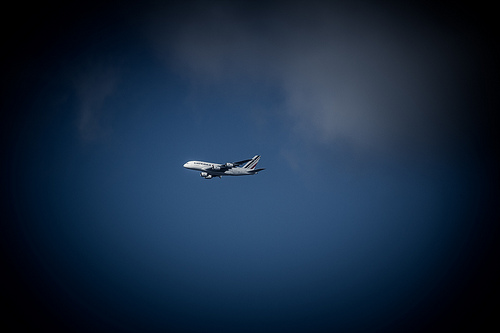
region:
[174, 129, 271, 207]
airplane flying in the sky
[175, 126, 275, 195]
airplane flying in the sky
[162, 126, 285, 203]
airplane flying in the sky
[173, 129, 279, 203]
airplane flying in the sky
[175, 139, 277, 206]
airplane flying in the sky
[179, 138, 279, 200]
airplane flying in the sky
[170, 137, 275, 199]
airplane flying in the sky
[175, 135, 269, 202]
airplane flying in the sky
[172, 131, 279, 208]
airplane flying in the sky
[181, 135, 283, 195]
airplane flying in the sky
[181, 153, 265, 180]
small white passenger plane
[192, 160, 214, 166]
line of windows on an airplane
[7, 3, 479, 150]
white clouds in the sky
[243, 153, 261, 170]
dark stripes on tail fin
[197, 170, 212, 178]
two round airplane engines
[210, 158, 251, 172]
two engines underneath a wing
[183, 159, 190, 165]
windows of the cockpit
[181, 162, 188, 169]
white rounded nose of an airplane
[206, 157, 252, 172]
dark underside of airplane wing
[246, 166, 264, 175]
small back wing section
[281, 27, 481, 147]
cloud in the sky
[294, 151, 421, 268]
clear part of the sky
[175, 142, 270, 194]
airplane in the sky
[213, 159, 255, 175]
the wing of a airplane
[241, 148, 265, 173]
the tail of an airplane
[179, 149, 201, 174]
the nose of an airplane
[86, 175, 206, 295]
a clear part of the sky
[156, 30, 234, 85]
cloud in the sky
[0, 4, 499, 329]
photo focused on airplane in the sky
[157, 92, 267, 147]
clear part of the sky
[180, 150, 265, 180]
airplane in the sky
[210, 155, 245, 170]
wing of a plane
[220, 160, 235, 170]
engine of a plane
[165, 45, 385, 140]
part of a cloudy sky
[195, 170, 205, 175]
right engine of a plane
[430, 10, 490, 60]
black area of an image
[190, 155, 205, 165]
writings on side of plane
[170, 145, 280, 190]
plane flying high.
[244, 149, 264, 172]
tale of an airplane.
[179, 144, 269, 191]
Plane in the air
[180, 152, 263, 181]
Plane is in the air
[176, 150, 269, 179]
Airplane in the air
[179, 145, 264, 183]
Airplane is in the air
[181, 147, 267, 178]
Plane flying in the air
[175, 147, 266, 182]
Plane is flying in the air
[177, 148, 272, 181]
Airplane flying in the air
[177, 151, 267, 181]
Airplane is flying in the air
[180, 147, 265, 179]
White plane in the air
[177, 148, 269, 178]
White airplane is in the air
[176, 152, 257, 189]
white airplane in the sky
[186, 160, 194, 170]
small frontal part of the airplane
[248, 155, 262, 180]
rear spoiler of the airplane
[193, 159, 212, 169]
small lateral windows of the airplane